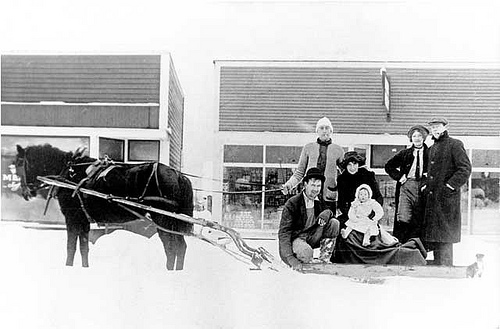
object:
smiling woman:
[385, 124, 430, 244]